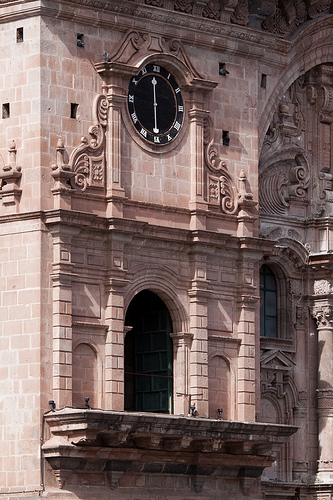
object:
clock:
[125, 62, 185, 149]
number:
[152, 63, 156, 72]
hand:
[151, 107, 160, 137]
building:
[0, 4, 333, 499]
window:
[122, 280, 180, 412]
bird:
[217, 66, 231, 75]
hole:
[217, 59, 230, 80]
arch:
[258, 45, 333, 480]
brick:
[51, 286, 72, 302]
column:
[103, 72, 128, 219]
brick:
[51, 299, 65, 315]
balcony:
[42, 404, 300, 475]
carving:
[49, 93, 109, 198]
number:
[178, 104, 184, 110]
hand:
[150, 76, 159, 107]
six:
[153, 135, 161, 144]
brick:
[19, 345, 42, 363]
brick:
[53, 337, 71, 355]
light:
[47, 398, 57, 413]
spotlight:
[84, 396, 90, 409]